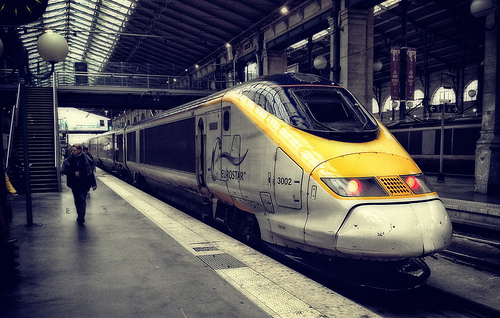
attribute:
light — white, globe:
[38, 32, 68, 62]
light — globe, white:
[36, 30, 69, 60]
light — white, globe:
[302, 45, 342, 75]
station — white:
[15, 15, 481, 306]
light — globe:
[364, 37, 403, 91]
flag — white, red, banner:
[368, 33, 439, 123]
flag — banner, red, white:
[383, 40, 449, 116]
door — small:
[263, 132, 328, 264]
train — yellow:
[80, 81, 484, 303]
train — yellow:
[90, 58, 452, 313]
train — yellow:
[70, 43, 453, 283]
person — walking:
[57, 129, 116, 254]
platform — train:
[10, 171, 198, 314]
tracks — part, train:
[454, 218, 484, 286]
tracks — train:
[447, 213, 481, 293]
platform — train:
[109, 229, 211, 297]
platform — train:
[14, 250, 92, 310]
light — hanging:
[34, 28, 101, 103]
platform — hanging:
[420, 155, 481, 197]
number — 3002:
[249, 149, 306, 206]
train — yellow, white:
[114, 60, 455, 275]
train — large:
[92, 90, 498, 256]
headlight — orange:
[337, 175, 358, 207]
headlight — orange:
[399, 170, 421, 197]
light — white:
[29, 31, 69, 71]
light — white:
[293, 52, 335, 80]